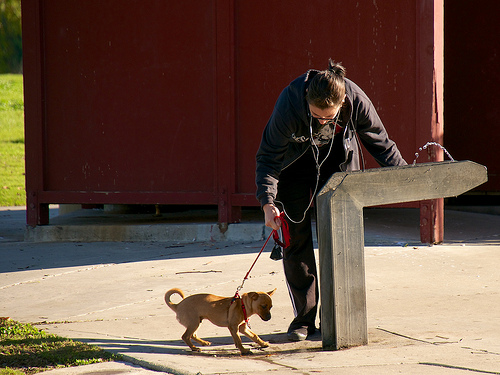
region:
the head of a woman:
[283, 60, 383, 140]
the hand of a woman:
[253, 198, 300, 260]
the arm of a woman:
[245, 88, 306, 213]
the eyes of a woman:
[303, 95, 358, 129]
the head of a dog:
[246, 275, 298, 342]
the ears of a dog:
[233, 255, 315, 305]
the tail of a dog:
[153, 268, 215, 330]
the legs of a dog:
[166, 320, 287, 358]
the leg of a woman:
[274, 183, 349, 345]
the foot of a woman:
[265, 276, 338, 366]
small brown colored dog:
[171, 281, 283, 338]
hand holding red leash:
[218, 208, 289, 312]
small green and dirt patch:
[3, 325, 110, 360]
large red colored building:
[21, 21, 215, 233]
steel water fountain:
[311, 150, 475, 345]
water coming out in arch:
[400, 140, 473, 174]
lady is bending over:
[291, 69, 389, 199]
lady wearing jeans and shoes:
[272, 264, 329, 351]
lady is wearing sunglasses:
[302, 93, 339, 132]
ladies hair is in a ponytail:
[321, 51, 349, 93]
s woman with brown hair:
[302, 59, 347, 123]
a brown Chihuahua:
[164, 288, 276, 353]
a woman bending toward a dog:
[256, 59, 408, 343]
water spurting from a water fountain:
[411, 137, 455, 167]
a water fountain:
[317, 143, 487, 355]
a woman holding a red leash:
[233, 204, 290, 327]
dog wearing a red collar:
[239, 295, 249, 322]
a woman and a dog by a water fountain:
[163, 57, 488, 352]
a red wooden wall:
[20, 1, 445, 234]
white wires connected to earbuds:
[273, 93, 346, 222]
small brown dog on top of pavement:
[164, 288, 269, 351]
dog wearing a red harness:
[228, 291, 248, 324]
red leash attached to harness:
[239, 212, 291, 284]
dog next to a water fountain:
[315, 159, 486, 346]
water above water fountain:
[411, 141, 456, 165]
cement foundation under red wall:
[26, 212, 281, 241]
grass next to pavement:
[0, 315, 111, 374]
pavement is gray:
[0, 206, 499, 373]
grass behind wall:
[1, 73, 23, 205]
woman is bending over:
[253, 56, 402, 338]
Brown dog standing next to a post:
[161, 284, 278, 356]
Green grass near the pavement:
[0, 313, 122, 373]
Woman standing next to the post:
[258, 56, 411, 344]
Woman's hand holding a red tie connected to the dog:
[257, 201, 288, 233]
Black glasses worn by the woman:
[305, 111, 338, 125]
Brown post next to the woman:
[312, 155, 490, 357]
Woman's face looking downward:
[306, 62, 347, 127]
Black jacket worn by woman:
[255, 68, 409, 211]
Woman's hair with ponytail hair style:
[302, 58, 352, 110]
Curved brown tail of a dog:
[162, 286, 187, 311]